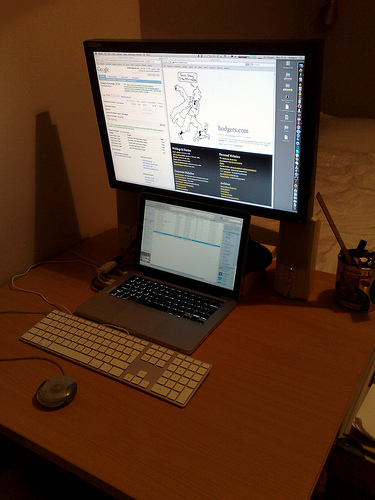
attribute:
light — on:
[277, 252, 298, 277]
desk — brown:
[242, 348, 294, 419]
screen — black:
[64, 47, 309, 212]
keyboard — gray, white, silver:
[37, 312, 205, 400]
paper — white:
[129, 82, 165, 119]